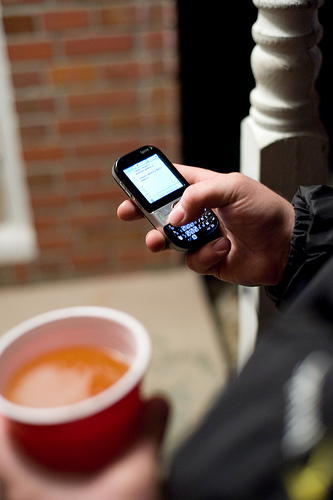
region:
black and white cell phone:
[115, 136, 228, 244]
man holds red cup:
[33, 328, 150, 482]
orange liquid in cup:
[17, 325, 143, 405]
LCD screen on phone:
[128, 149, 175, 207]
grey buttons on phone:
[151, 202, 185, 225]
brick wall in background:
[22, 11, 168, 249]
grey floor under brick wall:
[52, 246, 211, 384]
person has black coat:
[293, 171, 330, 274]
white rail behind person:
[229, 13, 320, 171]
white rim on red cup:
[10, 317, 134, 416]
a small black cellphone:
[94, 144, 196, 225]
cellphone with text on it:
[121, 154, 185, 214]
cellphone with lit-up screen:
[113, 146, 202, 233]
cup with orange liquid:
[28, 324, 166, 443]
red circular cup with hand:
[17, 388, 167, 473]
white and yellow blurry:
[263, 352, 325, 493]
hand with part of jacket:
[249, 163, 320, 283]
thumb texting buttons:
[164, 183, 221, 257]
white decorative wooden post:
[228, 13, 317, 215]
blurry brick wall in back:
[4, 62, 177, 218]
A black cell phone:
[104, 138, 226, 254]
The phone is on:
[111, 140, 225, 259]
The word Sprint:
[138, 148, 152, 155]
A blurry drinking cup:
[0, 310, 158, 473]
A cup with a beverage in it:
[0, 314, 153, 460]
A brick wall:
[19, 15, 177, 142]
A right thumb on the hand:
[169, 172, 266, 225]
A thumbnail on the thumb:
[167, 202, 188, 221]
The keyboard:
[180, 217, 215, 238]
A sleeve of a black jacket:
[288, 187, 330, 302]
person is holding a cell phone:
[97, 129, 317, 369]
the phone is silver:
[96, 112, 238, 244]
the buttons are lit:
[162, 210, 207, 247]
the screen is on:
[106, 141, 181, 196]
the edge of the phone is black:
[101, 134, 188, 196]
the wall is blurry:
[58, 2, 178, 251]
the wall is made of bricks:
[3, 1, 178, 263]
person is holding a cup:
[11, 304, 197, 477]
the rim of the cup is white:
[3, 282, 158, 433]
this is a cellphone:
[96, 133, 231, 251]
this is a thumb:
[168, 159, 236, 235]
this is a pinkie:
[177, 224, 243, 282]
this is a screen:
[119, 152, 184, 205]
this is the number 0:
[190, 232, 204, 241]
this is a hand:
[115, 143, 305, 307]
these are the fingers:
[115, 160, 231, 267]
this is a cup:
[1, 306, 186, 474]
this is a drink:
[34, 355, 82, 394]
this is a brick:
[50, 130, 78, 179]